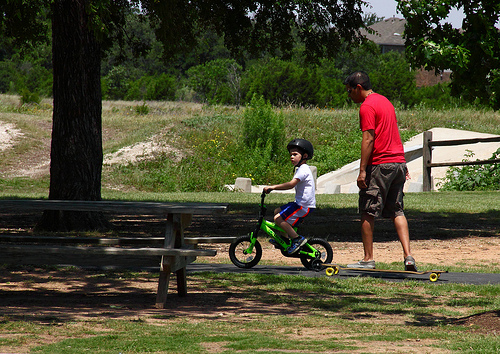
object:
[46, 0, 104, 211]
tree trunk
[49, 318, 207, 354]
patchy grass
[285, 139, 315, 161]
helmet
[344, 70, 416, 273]
man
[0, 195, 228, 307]
picnic table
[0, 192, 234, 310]
table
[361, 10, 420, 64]
building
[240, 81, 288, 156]
trees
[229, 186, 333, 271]
bike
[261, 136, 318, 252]
boy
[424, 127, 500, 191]
fence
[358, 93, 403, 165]
shirt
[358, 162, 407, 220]
shorts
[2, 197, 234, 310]
bench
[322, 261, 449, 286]
skateboard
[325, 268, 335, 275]
yellow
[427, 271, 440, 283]
wheels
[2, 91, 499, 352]
park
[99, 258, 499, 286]
sidewalk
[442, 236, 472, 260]
dirt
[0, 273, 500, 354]
ground